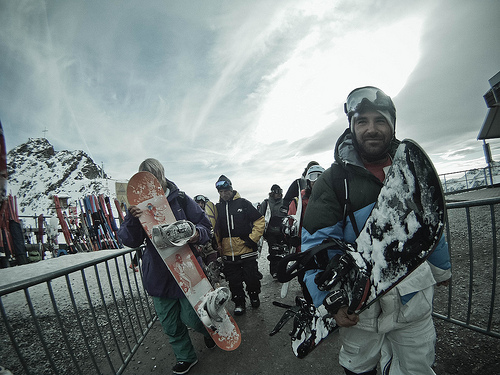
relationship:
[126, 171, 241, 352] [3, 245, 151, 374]
snowboard along a fence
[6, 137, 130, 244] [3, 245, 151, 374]
hill behind fence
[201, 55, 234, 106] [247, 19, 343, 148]
breaks in clouds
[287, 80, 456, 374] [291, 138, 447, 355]
man carrying a snowboard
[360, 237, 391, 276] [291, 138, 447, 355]
snow under snowboard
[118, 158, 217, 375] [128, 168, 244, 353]
people carrying a snowboard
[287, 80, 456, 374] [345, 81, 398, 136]
man wearing a snowhat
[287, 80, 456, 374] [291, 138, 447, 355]
person holding snowboard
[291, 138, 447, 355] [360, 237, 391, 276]
snowboard covered in snow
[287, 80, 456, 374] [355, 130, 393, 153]
man with a beard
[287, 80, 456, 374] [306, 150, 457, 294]
man wearing a blue & black jacket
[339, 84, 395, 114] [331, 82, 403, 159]
goggles on h head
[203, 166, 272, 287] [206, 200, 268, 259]
man wearing a yellow jacket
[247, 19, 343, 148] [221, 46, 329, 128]
clouds in sky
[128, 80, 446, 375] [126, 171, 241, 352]
people walking with snowboard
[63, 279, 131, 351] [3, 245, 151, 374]
rails on a fence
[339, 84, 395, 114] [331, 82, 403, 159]
goggles on mans head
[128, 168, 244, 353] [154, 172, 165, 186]
snowboard covering face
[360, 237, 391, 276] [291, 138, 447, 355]
snow on snowboard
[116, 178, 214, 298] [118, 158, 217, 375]
jacket on a people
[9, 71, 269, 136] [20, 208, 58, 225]
skies with bottom of a mountain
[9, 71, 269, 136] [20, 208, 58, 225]
skies in front of a mountain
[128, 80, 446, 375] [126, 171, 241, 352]
snowboarders with snowboard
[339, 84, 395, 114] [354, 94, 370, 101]
goggles on a pair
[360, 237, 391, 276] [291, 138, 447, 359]
snow on snowboard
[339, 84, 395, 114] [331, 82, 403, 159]
goggles on head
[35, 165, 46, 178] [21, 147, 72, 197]
snow on hill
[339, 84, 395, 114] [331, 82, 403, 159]
goggles are on head